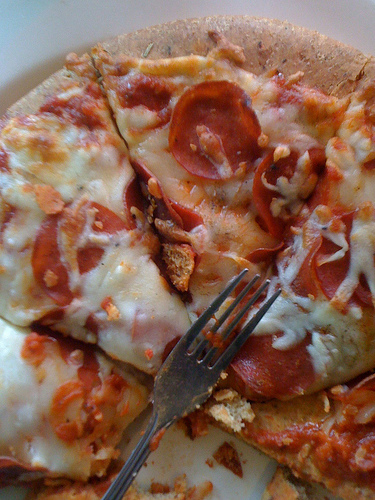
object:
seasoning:
[144, 42, 153, 57]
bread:
[3, 5, 374, 151]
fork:
[100, 268, 283, 500]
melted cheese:
[0, 175, 183, 437]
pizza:
[0, 10, 375, 500]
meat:
[29, 79, 370, 397]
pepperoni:
[32, 76, 372, 400]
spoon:
[138, 265, 290, 360]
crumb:
[35, 185, 65, 215]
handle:
[100, 414, 179, 500]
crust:
[0, 17, 375, 117]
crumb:
[95, 221, 104, 230]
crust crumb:
[1, 16, 373, 497]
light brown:
[0, 46, 66, 111]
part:
[213, 290, 280, 369]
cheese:
[84, 248, 182, 362]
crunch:
[205, 458, 213, 468]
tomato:
[201, 106, 219, 144]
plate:
[154, 444, 201, 472]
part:
[277, 61, 294, 70]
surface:
[173, 428, 279, 495]